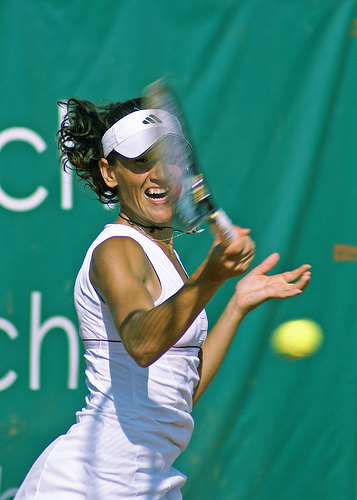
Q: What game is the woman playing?
A: Tennis.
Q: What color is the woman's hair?
A: Brown.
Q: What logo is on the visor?
A: Adidas.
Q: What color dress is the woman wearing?
A: White.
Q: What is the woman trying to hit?
A: Ball.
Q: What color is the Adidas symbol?
A: Blue.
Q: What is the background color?
A: Green.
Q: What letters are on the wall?
A: C h.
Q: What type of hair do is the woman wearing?
A: Ponytail.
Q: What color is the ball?
A: Yellow.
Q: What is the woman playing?
A: Tennis.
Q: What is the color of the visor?
A: White.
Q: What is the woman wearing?
A: Dress.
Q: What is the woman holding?
A: A racket.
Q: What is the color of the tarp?
A: Green.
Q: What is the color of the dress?
A: White.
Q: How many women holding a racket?
A: One.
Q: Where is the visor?
A: On the woman's head.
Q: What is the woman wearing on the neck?
A: Necklace.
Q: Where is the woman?
A: In tennis court.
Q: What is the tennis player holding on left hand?
A: A racket.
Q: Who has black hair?
A: Tennis player.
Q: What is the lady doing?
A: Playing tennis.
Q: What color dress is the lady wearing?
A: White.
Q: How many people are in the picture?
A: 1.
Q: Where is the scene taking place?
A: Tennis court.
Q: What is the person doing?
A: Hitting tennis ball.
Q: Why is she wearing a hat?
A: Keep sun out of eyes.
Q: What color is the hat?
A: White.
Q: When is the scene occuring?
A: Daytime.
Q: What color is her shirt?
A: White.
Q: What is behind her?
A: A partial banner.